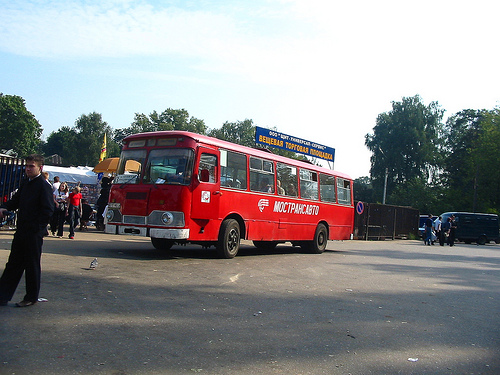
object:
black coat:
[5, 175, 58, 240]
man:
[0, 154, 58, 307]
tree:
[364, 93, 449, 204]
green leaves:
[438, 112, 443, 117]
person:
[68, 183, 85, 237]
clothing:
[0, 175, 53, 301]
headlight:
[159, 211, 173, 224]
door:
[190, 145, 221, 219]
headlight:
[105, 208, 115, 221]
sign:
[354, 199, 364, 215]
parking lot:
[0, 224, 499, 373]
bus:
[102, 129, 355, 259]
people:
[424, 212, 436, 244]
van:
[433, 212, 499, 244]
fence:
[353, 203, 420, 242]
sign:
[199, 190, 211, 202]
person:
[53, 176, 71, 236]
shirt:
[52, 189, 69, 209]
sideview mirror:
[198, 166, 210, 182]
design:
[257, 197, 268, 210]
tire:
[218, 217, 241, 259]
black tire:
[216, 217, 241, 259]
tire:
[309, 223, 328, 254]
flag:
[98, 131, 106, 166]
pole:
[103, 128, 110, 157]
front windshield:
[115, 147, 193, 184]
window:
[152, 149, 187, 184]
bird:
[87, 255, 102, 270]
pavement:
[0, 225, 499, 374]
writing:
[272, 199, 320, 215]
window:
[249, 170, 274, 193]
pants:
[0, 229, 42, 298]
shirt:
[71, 191, 79, 206]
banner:
[253, 125, 335, 163]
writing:
[269, 129, 326, 149]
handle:
[214, 191, 224, 194]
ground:
[0, 224, 499, 374]